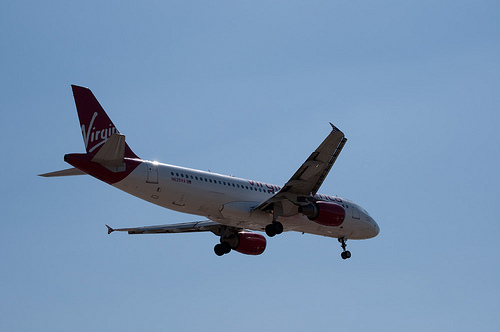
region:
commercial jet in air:
[23, 75, 375, 295]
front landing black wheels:
[330, 245, 350, 261]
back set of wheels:
[263, 222, 288, 239]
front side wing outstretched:
[293, 119, 365, 194]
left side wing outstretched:
[93, 220, 209, 240]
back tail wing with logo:
[66, 73, 152, 167]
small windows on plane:
[163, 166, 206, 183]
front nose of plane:
[352, 207, 386, 251]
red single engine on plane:
[234, 229, 271, 263]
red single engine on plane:
[308, 194, 345, 235]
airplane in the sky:
[21, 65, 380, 282]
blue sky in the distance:
[409, 30, 488, 308]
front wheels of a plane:
[329, 244, 365, 264]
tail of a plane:
[50, 73, 130, 160]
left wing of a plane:
[102, 219, 229, 241]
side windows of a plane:
[167, 165, 276, 193]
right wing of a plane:
[245, 106, 352, 220]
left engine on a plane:
[220, 223, 269, 264]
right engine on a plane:
[295, 190, 354, 234]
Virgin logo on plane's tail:
[70, 108, 120, 150]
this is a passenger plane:
[20, 34, 444, 285]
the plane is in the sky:
[20, 27, 452, 311]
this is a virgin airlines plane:
[15, 21, 469, 296]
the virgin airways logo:
[35, 62, 166, 226]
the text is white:
[32, 50, 149, 242]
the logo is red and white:
[24, 25, 224, 277]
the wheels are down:
[17, 41, 457, 322]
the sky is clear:
[211, 70, 289, 125]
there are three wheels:
[5, 44, 469, 312]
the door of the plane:
[131, 137, 168, 204]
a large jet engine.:
[216, 210, 271, 268]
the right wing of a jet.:
[253, 120, 351, 220]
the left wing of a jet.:
[95, 199, 275, 260]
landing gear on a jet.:
[326, 239, 364, 268]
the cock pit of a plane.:
[344, 199, 404, 243]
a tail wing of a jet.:
[75, 59, 134, 156]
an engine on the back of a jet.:
[49, 136, 101, 171]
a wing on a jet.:
[16, 166, 83, 198]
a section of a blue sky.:
[404, 71, 431, 89]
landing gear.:
[206, 239, 234, 271]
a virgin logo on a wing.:
[77, 68, 147, 156]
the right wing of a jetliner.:
[253, 113, 358, 217]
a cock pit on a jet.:
[343, 180, 391, 253]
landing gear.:
[201, 224, 247, 272]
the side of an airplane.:
[164, 157, 352, 213]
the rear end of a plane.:
[53, 146, 97, 173]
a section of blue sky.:
[391, 49, 451, 97]